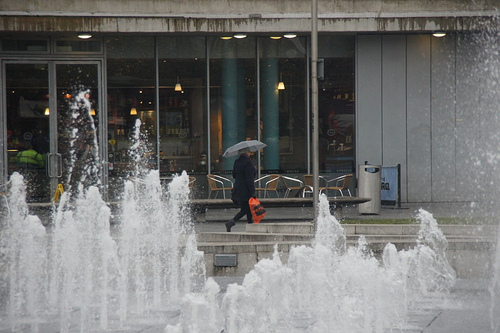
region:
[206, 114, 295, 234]
Woman is passing in front of building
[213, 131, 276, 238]
Woman holds an umbrella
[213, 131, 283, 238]
Person holds an orange bag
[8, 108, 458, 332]
Water fountain in front of building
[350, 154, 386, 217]
Trash can is tan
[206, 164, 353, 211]
Chairs in front of building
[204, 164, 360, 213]
Chairs are brown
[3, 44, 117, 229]
Door of building is made of glass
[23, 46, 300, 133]
Lamps inside the building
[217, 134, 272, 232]
Woman wears black outfit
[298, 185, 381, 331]
outdoor water fountain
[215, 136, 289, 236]
person walking with an umbrella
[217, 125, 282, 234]
person carrying a bright orange shopping bag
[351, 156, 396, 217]
silver garbage placed outside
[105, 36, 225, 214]
large tall glass windows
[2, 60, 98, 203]
large tall glass doors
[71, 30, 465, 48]
circle lights in the ceiling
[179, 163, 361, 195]
lots of chairs outside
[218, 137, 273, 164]
light grey open umberella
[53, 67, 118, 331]
tall splashes of water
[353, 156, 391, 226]
Tan colored trash can in background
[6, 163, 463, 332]
Water is in the foreground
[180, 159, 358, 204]
Brown chairs are in the background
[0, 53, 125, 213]
Glass door is in the background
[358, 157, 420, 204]
Powder blue sign in the background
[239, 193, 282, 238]
Person is holding a orange bag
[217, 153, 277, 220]
Person has on a black coat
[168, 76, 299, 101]
Lights are inside store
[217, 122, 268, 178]
Person is holding a umbrella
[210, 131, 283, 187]
umbrella is dark gray in color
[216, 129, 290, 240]
person carrying an umbrella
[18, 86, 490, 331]
water gushing from a fountain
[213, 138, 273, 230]
person in all black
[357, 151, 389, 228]
a gray trashcan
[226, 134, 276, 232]
person carrying an orange bag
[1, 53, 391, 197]
a building with glass windows and doors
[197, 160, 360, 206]
a row of chairs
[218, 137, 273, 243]
a person walking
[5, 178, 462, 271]
water special effects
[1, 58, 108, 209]
glass doors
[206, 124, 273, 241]
Person carrying umbrella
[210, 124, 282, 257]
Person carrying grey umbrella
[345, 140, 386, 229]
silver metal garbage can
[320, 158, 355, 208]
Brown metal chair with silver arms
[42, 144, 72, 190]
Silver metal door handle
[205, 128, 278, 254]
Person carrying red shopping bag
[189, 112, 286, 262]
Person with shopping bag and umbrella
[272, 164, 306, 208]
Brown chair with metal arms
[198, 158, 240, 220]
Brown chair with metal arms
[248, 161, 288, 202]
Brown chair with metal arms